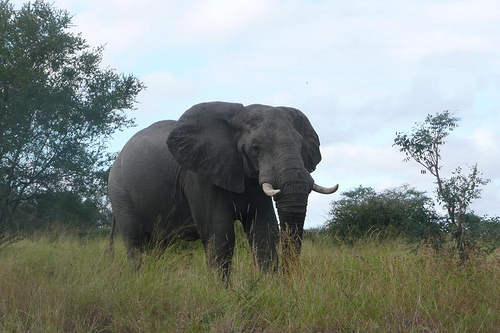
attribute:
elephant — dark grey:
[103, 100, 340, 284]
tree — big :
[391, 108, 488, 289]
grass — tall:
[165, 261, 412, 326]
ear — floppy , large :
[164, 101, 247, 195]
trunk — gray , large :
[268, 156, 310, 271]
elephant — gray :
[83, 84, 332, 300]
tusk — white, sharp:
[311, 182, 339, 194]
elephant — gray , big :
[85, 97, 344, 294]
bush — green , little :
[319, 180, 452, 249]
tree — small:
[392, 103, 492, 261]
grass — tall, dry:
[4, 241, 497, 332]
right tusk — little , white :
[261, 182, 280, 197]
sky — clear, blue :
[0, 2, 498, 232]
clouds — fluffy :
[4, 0, 499, 220]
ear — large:
[162, 93, 244, 195]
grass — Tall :
[362, 207, 435, 263]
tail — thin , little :
[76, 194, 129, 251]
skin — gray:
[135, 138, 216, 200]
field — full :
[1, 221, 497, 325]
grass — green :
[1, 232, 491, 331]